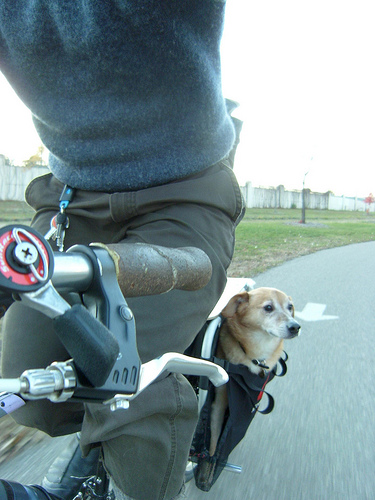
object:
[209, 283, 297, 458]
dog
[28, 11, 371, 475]
photo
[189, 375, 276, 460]
bag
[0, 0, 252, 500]
person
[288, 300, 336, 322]
arrow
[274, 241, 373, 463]
street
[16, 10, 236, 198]
sweater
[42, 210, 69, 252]
keys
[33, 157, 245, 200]
waist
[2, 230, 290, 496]
bike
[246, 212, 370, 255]
grass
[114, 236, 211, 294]
handle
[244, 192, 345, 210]
fence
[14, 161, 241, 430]
pants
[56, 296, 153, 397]
grip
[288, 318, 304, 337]
nose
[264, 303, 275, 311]
eyes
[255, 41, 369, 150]
background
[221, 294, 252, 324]
ears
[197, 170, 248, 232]
pocket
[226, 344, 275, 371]
collar